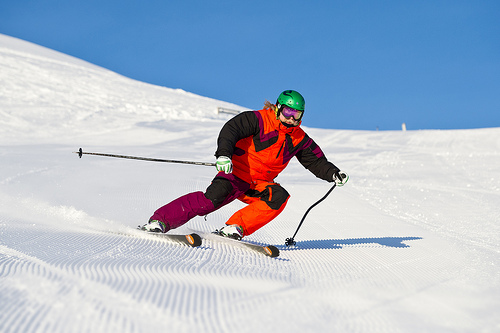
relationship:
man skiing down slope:
[138, 89, 348, 257] [0, 30, 498, 330]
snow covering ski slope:
[388, 205, 461, 280] [1, 35, 497, 327]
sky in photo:
[195, 19, 476, 84] [44, 42, 464, 290]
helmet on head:
[277, 87, 304, 108] [275, 87, 307, 129]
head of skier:
[275, 87, 307, 129] [141, 90, 350, 266]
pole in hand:
[72, 147, 233, 171] [213, 151, 240, 188]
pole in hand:
[50, 122, 229, 185] [204, 147, 244, 190]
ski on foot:
[143, 229, 203, 253] [140, 217, 167, 232]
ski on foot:
[209, 221, 320, 278] [210, 214, 243, 249]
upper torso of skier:
[175, 82, 329, 252] [58, 58, 495, 286]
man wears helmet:
[138, 89, 348, 257] [273, 85, 300, 105]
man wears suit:
[138, 89, 348, 257] [212, 125, 297, 229]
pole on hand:
[286, 181, 342, 242] [301, 132, 347, 184]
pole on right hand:
[72, 147, 233, 171] [212, 155, 234, 173]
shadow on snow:
[237, 233, 427, 262] [5, 27, 493, 329]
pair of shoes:
[121, 211, 271, 257] [137, 212, 248, 242]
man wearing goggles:
[117, 87, 347, 257] [260, 99, 327, 122]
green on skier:
[289, 97, 296, 104] [64, 60, 362, 260]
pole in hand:
[285, 174, 346, 245] [332, 171, 349, 187]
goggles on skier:
[274, 103, 306, 127] [118, 51, 358, 261]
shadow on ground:
[235, 236, 425, 262] [109, 247, 366, 307]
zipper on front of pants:
[193, 190, 243, 220] [148, 170, 292, 236]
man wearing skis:
[138, 89, 348, 257] [119, 207, 273, 257]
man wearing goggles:
[138, 89, 348, 257] [273, 101, 305, 122]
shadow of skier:
[235, 236, 425, 262] [138, 88, 340, 236]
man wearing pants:
[138, 89, 348, 257] [148, 167, 292, 238]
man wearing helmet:
[138, 89, 348, 257] [272, 86, 308, 118]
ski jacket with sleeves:
[216, 110, 343, 186] [217, 111, 343, 184]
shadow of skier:
[235, 236, 425, 262] [143, 87, 344, 246]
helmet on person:
[277, 89, 306, 112] [181, 75, 348, 257]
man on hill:
[138, 89, 348, 257] [41, 49, 106, 59]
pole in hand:
[72, 147, 233, 171] [215, 156, 232, 173]